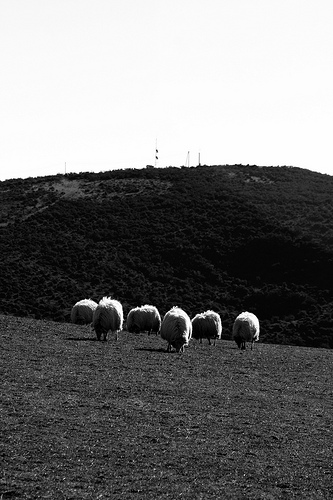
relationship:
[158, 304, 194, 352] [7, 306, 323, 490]
sheep in field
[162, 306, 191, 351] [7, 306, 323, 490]
sheep in field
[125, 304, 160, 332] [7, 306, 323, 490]
sheep in field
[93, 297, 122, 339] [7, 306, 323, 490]
sheep in field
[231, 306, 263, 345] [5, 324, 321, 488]
sheep on grass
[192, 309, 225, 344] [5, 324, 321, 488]
sheep on grass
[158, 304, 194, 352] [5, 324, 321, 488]
sheep on grass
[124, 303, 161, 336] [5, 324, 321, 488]
sheep on grass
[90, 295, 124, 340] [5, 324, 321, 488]
sheep on grass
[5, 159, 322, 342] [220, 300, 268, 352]
mountain behind sheep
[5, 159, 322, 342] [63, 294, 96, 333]
mountain behind sheep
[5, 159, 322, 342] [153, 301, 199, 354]
mountain behind sheep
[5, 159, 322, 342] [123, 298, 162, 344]
mountain behind sheep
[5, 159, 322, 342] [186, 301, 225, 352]
mountain behind sheep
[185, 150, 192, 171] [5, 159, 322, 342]
pole top of mountain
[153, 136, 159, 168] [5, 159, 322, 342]
pole top of mountain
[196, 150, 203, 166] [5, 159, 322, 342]
pole top of mountain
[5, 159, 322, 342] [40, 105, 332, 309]
mountain has vegetation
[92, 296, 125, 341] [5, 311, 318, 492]
sheep eats grass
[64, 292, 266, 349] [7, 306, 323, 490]
group grazing on field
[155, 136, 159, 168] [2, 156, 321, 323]
pole top of hill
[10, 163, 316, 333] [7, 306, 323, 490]
formation before field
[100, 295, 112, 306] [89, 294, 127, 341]
white fur top of sheep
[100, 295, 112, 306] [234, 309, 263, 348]
white fur top of sheep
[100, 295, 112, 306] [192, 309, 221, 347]
white fur top of sheep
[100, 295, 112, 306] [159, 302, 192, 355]
white fur top of sheep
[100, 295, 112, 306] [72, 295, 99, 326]
white fur top of sheep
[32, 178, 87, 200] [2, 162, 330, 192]
spot on hilltop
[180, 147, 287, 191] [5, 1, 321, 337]
hill in background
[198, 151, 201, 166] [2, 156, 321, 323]
pole on hill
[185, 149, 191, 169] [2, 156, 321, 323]
pole on hill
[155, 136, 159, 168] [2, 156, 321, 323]
pole on hill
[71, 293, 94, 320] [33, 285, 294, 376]
sheep in field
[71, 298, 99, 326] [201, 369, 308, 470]
sheep in field